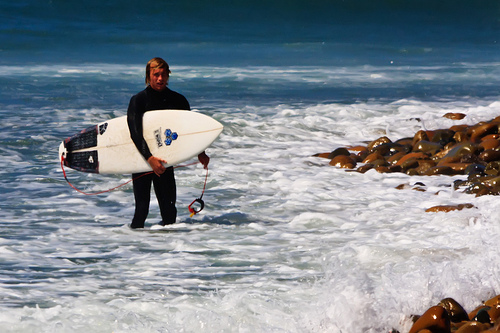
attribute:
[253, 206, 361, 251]
waves — white ocean , blue  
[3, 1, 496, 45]
sky —  blue  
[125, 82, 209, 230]
wet suit — black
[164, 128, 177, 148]
design — blue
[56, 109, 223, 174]
surfboard — white, black 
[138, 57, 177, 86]
hair — blonde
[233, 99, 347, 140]
foamy surf — white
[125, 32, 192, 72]
hair — wet, blonde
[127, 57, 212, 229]
surfer — black 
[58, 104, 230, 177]
board — white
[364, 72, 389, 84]
waves — blue  , white ocean 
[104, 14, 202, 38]
clouds — white 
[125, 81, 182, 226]
wetsuit — black